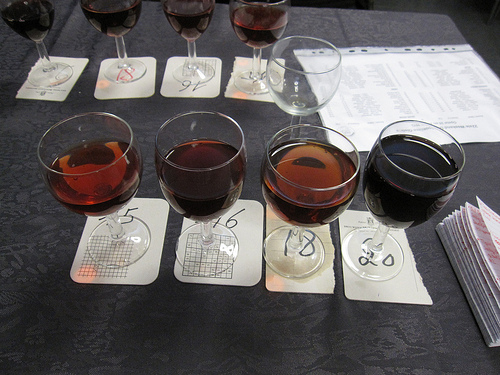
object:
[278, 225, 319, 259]
number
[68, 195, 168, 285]
place holder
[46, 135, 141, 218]
liquid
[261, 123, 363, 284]
glass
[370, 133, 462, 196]
red wine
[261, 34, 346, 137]
glass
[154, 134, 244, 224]
wine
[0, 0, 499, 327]
ground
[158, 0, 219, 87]
glasses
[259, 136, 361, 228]
liquid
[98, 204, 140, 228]
15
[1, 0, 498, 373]
table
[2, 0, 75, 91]
glasses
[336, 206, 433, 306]
coaster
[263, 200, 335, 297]
coaster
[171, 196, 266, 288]
coaster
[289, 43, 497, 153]
paper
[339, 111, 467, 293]
flower petal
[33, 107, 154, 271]
glass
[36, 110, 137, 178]
rim glass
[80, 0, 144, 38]
wine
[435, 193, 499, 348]
notebook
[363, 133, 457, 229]
liquid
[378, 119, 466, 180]
rim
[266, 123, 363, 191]
rim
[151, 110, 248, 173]
rim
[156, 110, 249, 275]
glass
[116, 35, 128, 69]
handle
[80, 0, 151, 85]
glass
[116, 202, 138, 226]
number '5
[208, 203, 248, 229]
number '16'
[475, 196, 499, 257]
notes